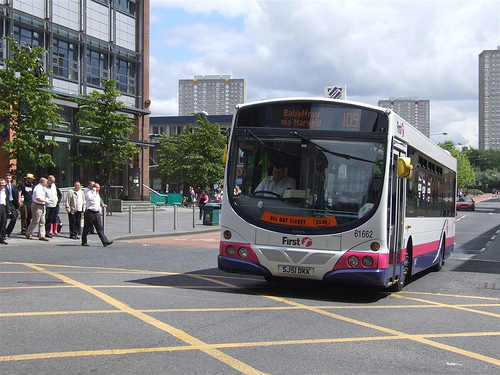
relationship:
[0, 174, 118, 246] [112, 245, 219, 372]
people walking on road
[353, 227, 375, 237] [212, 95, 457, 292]
numbers on bus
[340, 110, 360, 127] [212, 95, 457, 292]
numbers on bus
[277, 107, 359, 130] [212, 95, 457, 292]
lcd on bus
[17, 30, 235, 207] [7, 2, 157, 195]
trees on building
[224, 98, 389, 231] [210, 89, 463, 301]
windshield on bus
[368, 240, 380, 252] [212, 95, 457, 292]
headlight on bus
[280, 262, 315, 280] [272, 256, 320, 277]
plate on bus